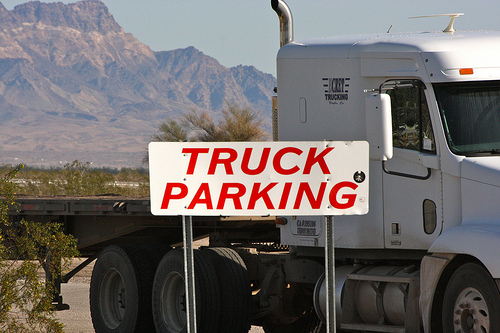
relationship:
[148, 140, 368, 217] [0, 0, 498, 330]
sign directing truck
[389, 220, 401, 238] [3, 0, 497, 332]
handle on semi truck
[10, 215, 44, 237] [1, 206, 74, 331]
green leaves of bush